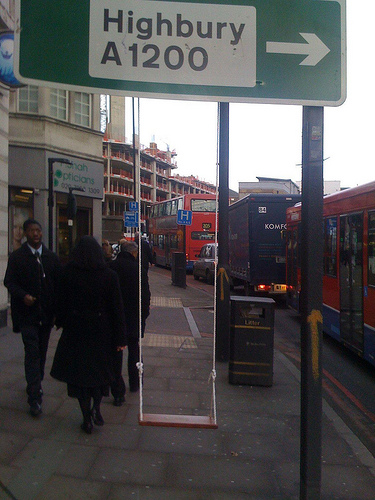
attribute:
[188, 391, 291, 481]
gray ground — grey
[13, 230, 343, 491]
ground — gray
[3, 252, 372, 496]
ground — gray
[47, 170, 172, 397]
people — walking 